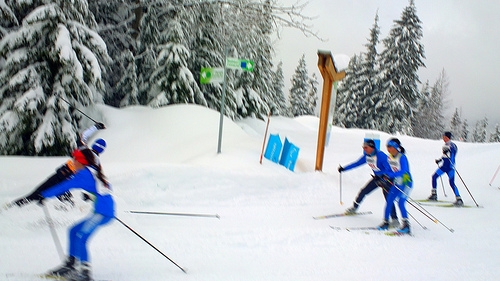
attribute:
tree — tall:
[382, 0, 432, 133]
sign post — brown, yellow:
[312, 77, 333, 171]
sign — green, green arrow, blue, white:
[225, 55, 261, 73]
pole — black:
[124, 206, 219, 221]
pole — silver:
[395, 185, 459, 238]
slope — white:
[11, 163, 499, 275]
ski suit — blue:
[375, 154, 414, 217]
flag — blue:
[260, 130, 286, 165]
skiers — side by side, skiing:
[336, 128, 427, 236]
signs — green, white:
[196, 54, 258, 86]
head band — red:
[72, 148, 88, 167]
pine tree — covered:
[2, 4, 107, 146]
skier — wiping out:
[23, 138, 101, 203]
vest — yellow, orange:
[67, 155, 75, 170]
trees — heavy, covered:
[3, 2, 436, 136]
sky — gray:
[266, 4, 497, 87]